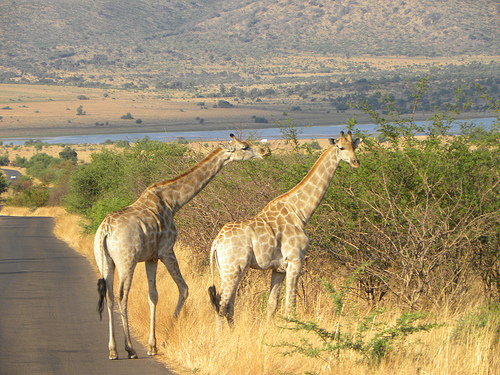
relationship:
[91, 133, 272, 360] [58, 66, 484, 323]
animal looking for food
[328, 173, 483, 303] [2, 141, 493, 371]
stems of bushes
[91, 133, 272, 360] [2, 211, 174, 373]
animal on road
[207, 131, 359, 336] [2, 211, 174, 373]
animal by road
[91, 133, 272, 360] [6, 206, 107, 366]
animal standing on road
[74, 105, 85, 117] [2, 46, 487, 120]
bush planted in dirt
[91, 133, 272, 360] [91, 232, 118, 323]
animal has tail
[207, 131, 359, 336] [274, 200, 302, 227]
animal has spots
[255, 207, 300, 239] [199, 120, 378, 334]
spots on animal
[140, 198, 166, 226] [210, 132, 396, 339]
spots on animal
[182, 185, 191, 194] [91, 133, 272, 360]
spot on animal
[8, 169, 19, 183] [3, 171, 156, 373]
vehicle on road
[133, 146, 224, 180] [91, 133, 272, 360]
mane on animal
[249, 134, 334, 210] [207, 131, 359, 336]
mane on animal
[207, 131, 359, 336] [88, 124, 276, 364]
animal next to giraffe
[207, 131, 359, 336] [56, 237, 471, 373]
animal standing grass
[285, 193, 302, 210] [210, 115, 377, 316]
spots on animal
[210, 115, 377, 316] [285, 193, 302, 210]
animal has spots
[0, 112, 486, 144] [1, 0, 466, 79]
water in distance